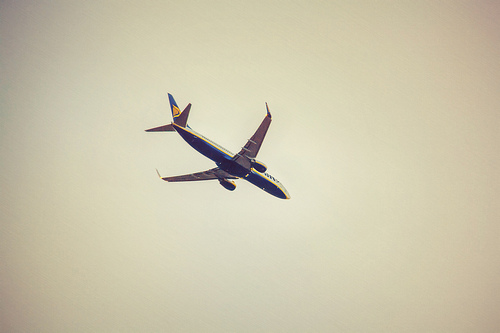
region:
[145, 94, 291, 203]
Plane flying through the sky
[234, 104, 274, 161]
The wing of a plane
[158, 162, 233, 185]
A wing on a plane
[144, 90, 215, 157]
Back end of a plane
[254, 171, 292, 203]
Front end of a plane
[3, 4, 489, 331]
A gray, dreary sky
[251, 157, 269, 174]
Engine on a plane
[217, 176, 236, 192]
An engine of a plane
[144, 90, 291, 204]
Underside of a flying plane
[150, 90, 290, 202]
an airplane flying through the sky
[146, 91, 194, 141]
the blue and yellow tail of an airplane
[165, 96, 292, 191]
wings of an airplane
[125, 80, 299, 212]
an airplane in the gray sky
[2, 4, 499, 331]
gray sky surrounding the airplane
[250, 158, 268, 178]
a propeller engine on the plane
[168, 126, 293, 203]
blue underbelly of the plane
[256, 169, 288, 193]
windows on the side of the plane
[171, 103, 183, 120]
yellow logo on the tail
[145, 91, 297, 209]
blue and yellow plane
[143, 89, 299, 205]
plane flying through the gray sky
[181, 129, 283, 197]
dark blue underside of plane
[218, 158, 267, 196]
engines on the plane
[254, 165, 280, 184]
lettering on the plane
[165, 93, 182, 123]
blue and yellow tail on the plane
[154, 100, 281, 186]
flipped up tips on the plane's wings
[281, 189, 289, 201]
nose of the airplane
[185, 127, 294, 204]
white top half of the airplane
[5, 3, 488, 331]
gray sky the plane is flying through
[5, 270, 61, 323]
Small part of cloudy sky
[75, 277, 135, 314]
Small part of cloudy sky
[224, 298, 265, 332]
Small part of cloudy sky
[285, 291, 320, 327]
Small part of cloudy sky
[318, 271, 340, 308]
Small part of cloudy sky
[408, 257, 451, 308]
Small part of cloudy sky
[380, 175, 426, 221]
Small part of cloudy sky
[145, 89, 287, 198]
a blue and yellow airplane in sky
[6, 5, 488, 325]
a cloudy gray sky above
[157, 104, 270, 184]
the airplane's wings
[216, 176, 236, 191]
jet engine on left wing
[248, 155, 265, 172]
jet engine on right wing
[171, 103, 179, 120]
yellow logo on blue tail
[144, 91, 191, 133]
tail section of the airplane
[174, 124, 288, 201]
the airplane's fuselage painted blue and yellow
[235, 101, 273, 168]
the plane's right wing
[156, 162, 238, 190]
the plane's left wing